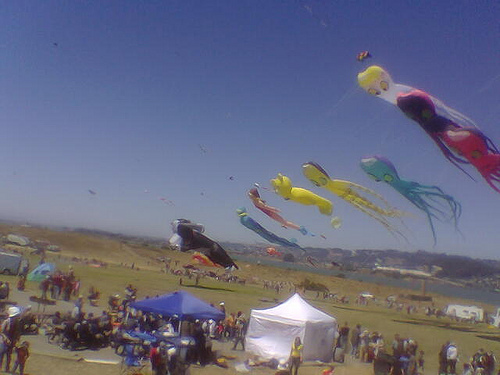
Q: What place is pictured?
A: It is a field.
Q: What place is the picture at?
A: It is at the field.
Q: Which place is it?
A: It is a field.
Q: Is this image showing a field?
A: Yes, it is showing a field.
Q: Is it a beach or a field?
A: It is a field.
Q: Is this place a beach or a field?
A: It is a field.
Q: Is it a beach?
A: No, it is a field.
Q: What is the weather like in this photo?
A: It is sunny.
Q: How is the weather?
A: It is sunny.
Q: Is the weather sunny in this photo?
A: Yes, it is sunny.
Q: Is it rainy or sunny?
A: It is sunny.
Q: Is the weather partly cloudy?
A: No, it is sunny.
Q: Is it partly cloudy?
A: No, it is sunny.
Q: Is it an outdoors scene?
A: Yes, it is outdoors.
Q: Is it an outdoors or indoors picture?
A: It is outdoors.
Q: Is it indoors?
A: No, it is outdoors.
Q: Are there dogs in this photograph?
A: Yes, there is a dog.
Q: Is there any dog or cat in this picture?
A: Yes, there is a dog.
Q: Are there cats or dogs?
A: Yes, there is a dog.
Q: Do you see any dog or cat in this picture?
A: Yes, there is a dog.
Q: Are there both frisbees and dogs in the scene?
A: No, there is a dog but no frisbees.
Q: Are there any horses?
A: No, there are no horses.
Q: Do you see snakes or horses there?
A: No, there are no horses or snakes.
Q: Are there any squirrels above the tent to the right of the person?
A: No, there is a dog above the tent.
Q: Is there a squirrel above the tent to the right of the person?
A: No, there is a dog above the tent.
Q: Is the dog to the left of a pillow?
A: No, the dog is to the left of a kite.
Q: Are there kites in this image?
A: Yes, there is a kite.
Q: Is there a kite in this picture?
A: Yes, there is a kite.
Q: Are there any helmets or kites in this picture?
A: Yes, there is a kite.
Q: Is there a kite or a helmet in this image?
A: Yes, there is a kite.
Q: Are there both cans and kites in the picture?
A: No, there is a kite but no cans.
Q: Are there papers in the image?
A: No, there are no papers.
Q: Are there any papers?
A: No, there are no papers.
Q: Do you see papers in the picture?
A: No, there are no papers.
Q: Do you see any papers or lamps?
A: No, there are no papers or lamps.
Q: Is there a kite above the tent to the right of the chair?
A: Yes, there is a kite above the tent.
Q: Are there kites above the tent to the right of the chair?
A: Yes, there is a kite above the tent.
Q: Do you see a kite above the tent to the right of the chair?
A: Yes, there is a kite above the tent.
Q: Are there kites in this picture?
A: Yes, there is a kite.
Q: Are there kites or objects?
A: Yes, there is a kite.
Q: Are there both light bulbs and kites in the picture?
A: No, there is a kite but no light bulbs.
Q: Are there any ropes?
A: No, there are no ropes.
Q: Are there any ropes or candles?
A: No, there are no ropes or candles.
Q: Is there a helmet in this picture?
A: No, there are no helmets.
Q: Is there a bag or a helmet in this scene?
A: No, there are no helmets or bags.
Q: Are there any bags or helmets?
A: No, there are no helmets or bags.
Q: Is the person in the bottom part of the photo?
A: Yes, the person is in the bottom of the image.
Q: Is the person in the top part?
A: No, the person is in the bottom of the image.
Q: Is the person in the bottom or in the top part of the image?
A: The person is in the bottom of the image.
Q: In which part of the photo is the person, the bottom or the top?
A: The person is in the bottom of the image.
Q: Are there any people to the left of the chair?
A: Yes, there is a person to the left of the chair.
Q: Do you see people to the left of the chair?
A: Yes, there is a person to the left of the chair.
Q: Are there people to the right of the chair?
A: No, the person is to the left of the chair.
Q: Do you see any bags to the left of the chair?
A: No, there is a person to the left of the chair.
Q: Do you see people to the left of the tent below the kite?
A: Yes, there is a person to the left of the tent.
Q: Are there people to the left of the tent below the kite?
A: Yes, there is a person to the left of the tent.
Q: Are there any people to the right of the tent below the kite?
A: No, the person is to the left of the tent.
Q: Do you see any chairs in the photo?
A: Yes, there is a chair.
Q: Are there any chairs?
A: Yes, there is a chair.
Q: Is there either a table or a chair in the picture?
A: Yes, there is a chair.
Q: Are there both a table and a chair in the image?
A: No, there is a chair but no tables.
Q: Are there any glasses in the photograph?
A: No, there are no glasses.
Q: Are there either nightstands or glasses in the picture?
A: No, there are no glasses or nightstands.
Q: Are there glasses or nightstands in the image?
A: No, there are no glasses or nightstands.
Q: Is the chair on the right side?
A: No, the chair is on the left of the image.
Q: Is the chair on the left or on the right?
A: The chair is on the left of the image.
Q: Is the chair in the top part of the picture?
A: No, the chair is in the bottom of the image.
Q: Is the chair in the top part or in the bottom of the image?
A: The chair is in the bottom of the image.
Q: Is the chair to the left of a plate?
A: No, the chair is to the left of a tent.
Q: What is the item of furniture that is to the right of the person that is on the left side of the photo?
A: The piece of furniture is a chair.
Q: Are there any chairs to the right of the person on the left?
A: Yes, there is a chair to the right of the person.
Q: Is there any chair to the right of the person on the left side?
A: Yes, there is a chair to the right of the person.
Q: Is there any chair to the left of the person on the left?
A: No, the chair is to the right of the person.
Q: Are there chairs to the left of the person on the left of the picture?
A: No, the chair is to the right of the person.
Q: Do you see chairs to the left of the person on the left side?
A: No, the chair is to the right of the person.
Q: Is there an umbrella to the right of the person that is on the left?
A: No, there is a chair to the right of the person.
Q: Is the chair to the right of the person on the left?
A: Yes, the chair is to the right of the person.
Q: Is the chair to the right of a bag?
A: No, the chair is to the right of the person.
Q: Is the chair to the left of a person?
A: No, the chair is to the right of a person.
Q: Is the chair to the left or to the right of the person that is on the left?
A: The chair is to the right of the person.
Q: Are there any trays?
A: No, there are no trays.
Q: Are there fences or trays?
A: No, there are no trays or fences.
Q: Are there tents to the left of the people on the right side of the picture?
A: Yes, there is a tent to the left of the people.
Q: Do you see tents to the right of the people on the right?
A: No, the tent is to the left of the people.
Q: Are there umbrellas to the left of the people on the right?
A: No, there is a tent to the left of the people.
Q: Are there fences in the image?
A: No, there are no fences.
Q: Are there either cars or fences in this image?
A: No, there are no fences or cars.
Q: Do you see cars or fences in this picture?
A: No, there are no fences or cars.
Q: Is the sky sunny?
A: Yes, the sky is sunny.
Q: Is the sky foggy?
A: No, the sky is sunny.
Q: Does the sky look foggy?
A: No, the sky is sunny.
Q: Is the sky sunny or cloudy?
A: The sky is sunny.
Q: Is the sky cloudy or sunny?
A: The sky is sunny.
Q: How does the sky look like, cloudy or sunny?
A: The sky is sunny.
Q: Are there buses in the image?
A: No, there are no buses.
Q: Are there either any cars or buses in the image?
A: No, there are no buses or cars.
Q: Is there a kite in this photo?
A: Yes, there is a kite.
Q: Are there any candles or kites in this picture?
A: Yes, there is a kite.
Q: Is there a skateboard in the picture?
A: No, there are no skateboards.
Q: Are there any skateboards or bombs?
A: No, there are no skateboards or bombs.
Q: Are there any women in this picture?
A: Yes, there is a woman.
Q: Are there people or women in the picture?
A: Yes, there is a woman.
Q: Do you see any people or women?
A: Yes, there is a woman.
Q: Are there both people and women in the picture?
A: Yes, there are both a woman and a person.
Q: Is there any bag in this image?
A: No, there are no bags.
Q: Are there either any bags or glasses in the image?
A: No, there are no bags or glasses.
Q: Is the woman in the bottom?
A: Yes, the woman is in the bottom of the image.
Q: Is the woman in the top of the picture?
A: No, the woman is in the bottom of the image.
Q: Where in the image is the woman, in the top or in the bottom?
A: The woman is in the bottom of the image.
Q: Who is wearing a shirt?
A: The woman is wearing a shirt.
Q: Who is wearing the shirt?
A: The woman is wearing a shirt.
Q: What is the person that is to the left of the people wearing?
A: The woman is wearing a shirt.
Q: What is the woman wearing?
A: The woman is wearing a shirt.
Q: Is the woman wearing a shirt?
A: Yes, the woman is wearing a shirt.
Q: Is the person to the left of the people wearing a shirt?
A: Yes, the woman is wearing a shirt.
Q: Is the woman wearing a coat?
A: No, the woman is wearing a shirt.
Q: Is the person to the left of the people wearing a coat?
A: No, the woman is wearing a shirt.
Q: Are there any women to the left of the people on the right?
A: Yes, there is a woman to the left of the people.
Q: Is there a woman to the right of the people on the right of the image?
A: No, the woman is to the left of the people.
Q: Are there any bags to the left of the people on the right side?
A: No, there is a woman to the left of the people.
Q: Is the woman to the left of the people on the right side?
A: Yes, the woman is to the left of the people.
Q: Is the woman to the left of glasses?
A: No, the woman is to the left of the people.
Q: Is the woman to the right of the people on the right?
A: No, the woman is to the left of the people.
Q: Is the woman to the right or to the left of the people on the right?
A: The woman is to the left of the people.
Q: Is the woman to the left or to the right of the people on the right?
A: The woman is to the left of the people.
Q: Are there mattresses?
A: No, there are no mattresses.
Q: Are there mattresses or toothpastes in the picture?
A: No, there are no mattresses or toothpastes.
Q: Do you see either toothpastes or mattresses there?
A: No, there are no mattresses or toothpastes.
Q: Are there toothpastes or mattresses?
A: No, there are no mattresses or toothpastes.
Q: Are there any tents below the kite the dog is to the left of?
A: Yes, there is a tent below the kite.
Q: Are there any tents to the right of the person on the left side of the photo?
A: Yes, there is a tent to the right of the person.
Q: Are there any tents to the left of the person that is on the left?
A: No, the tent is to the right of the person.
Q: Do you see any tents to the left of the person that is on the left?
A: No, the tent is to the right of the person.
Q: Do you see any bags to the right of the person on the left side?
A: No, there is a tent to the right of the person.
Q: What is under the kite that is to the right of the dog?
A: The tent is under the kite.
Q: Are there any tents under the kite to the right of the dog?
A: Yes, there is a tent under the kite.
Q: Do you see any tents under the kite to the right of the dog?
A: Yes, there is a tent under the kite.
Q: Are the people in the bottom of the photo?
A: Yes, the people are in the bottom of the image.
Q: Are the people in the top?
A: No, the people are in the bottom of the image.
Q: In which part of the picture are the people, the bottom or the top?
A: The people are in the bottom of the image.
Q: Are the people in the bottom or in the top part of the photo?
A: The people are in the bottom of the image.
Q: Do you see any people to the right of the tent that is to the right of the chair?
A: Yes, there are people to the right of the tent.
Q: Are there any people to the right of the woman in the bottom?
A: Yes, there are people to the right of the woman.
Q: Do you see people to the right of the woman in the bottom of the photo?
A: Yes, there are people to the right of the woman.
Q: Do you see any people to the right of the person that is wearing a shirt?
A: Yes, there are people to the right of the woman.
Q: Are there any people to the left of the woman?
A: No, the people are to the right of the woman.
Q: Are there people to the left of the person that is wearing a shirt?
A: No, the people are to the right of the woman.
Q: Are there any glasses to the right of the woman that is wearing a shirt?
A: No, there are people to the right of the woman.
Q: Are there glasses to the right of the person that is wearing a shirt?
A: No, there are people to the right of the woman.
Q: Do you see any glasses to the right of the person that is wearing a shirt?
A: No, there are people to the right of the woman.